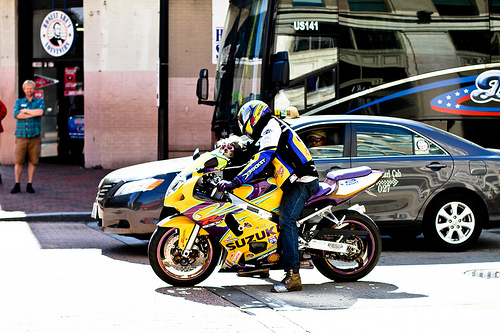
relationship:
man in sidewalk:
[7, 80, 46, 194] [7, 174, 92, 229]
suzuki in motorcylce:
[206, 212, 296, 262] [166, 160, 371, 291]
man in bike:
[216, 99, 320, 294] [147, 135, 385, 287]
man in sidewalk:
[0, 73, 57, 220] [2, 169, 109, 230]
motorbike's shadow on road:
[157, 280, 428, 310] [0, 220, 500, 331]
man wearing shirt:
[7, 80, 46, 194] [13, 95, 44, 136]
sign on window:
[26, 11, 100, 66] [19, 13, 150, 207]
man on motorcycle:
[216, 99, 320, 294] [148, 148, 383, 286]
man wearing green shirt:
[7, 80, 46, 194] [12, 97, 44, 136]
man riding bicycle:
[228, 96, 317, 287] [149, 99, 386, 295]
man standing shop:
[7, 80, 46, 194] [14, 12, 168, 174]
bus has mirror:
[192, 6, 499, 256] [194, 65, 210, 107]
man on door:
[7, 80, 46, 194] [6, 5, 91, 194]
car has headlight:
[86, 108, 499, 248] [111, 177, 166, 194]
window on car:
[352, 127, 444, 159] [213, 102, 497, 193]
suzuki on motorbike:
[224, 224, 281, 251] [133, 136, 403, 301]